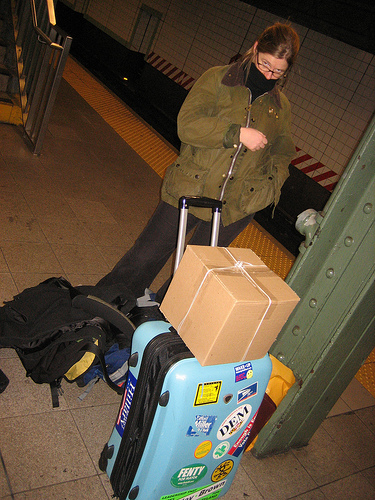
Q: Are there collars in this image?
A: Yes, there is a collar.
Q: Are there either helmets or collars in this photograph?
A: Yes, there is a collar.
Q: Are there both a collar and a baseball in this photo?
A: No, there is a collar but no baseballs.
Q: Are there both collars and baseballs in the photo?
A: No, there is a collar but no baseballs.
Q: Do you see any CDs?
A: No, there are no cds.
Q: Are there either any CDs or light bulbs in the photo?
A: No, there are no CDs or light bulbs.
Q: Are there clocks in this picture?
A: No, there are no clocks.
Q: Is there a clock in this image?
A: No, there are no clocks.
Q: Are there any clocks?
A: No, there are no clocks.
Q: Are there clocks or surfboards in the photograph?
A: No, there are no clocks or surfboards.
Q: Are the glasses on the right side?
A: Yes, the glasses are on the right of the image.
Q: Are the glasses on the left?
A: No, the glasses are on the right of the image.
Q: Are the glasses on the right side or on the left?
A: The glasses are on the right of the image.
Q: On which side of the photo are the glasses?
A: The glasses are on the right of the image.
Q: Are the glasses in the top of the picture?
A: Yes, the glasses are in the top of the image.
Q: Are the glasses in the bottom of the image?
A: No, the glasses are in the top of the image.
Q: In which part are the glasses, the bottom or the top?
A: The glasses are in the top of the image.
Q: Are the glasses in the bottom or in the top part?
A: The glasses are in the top of the image.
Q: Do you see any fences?
A: No, there are no fences.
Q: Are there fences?
A: No, there are no fences.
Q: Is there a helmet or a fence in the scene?
A: No, there are no fences or helmets.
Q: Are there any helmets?
A: No, there are no helmets.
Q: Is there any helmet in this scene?
A: No, there are no helmets.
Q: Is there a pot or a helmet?
A: No, there are no helmets or pots.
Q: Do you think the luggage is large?
A: Yes, the luggage is large.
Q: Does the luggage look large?
A: Yes, the luggage is large.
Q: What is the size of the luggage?
A: The luggage is large.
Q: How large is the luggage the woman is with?
A: The luggage is large.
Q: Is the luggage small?
A: No, the luggage is large.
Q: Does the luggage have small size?
A: No, the luggage is large.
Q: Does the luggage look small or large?
A: The luggage is large.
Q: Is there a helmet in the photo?
A: No, there are no helmets.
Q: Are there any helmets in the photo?
A: No, there are no helmets.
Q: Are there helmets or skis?
A: No, there are no helmets or skis.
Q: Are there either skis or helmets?
A: No, there are no helmets or skis.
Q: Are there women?
A: Yes, there is a woman.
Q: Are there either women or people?
A: Yes, there is a woman.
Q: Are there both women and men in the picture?
A: No, there is a woman but no men.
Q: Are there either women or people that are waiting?
A: Yes, the woman is waiting.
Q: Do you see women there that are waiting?
A: Yes, there is a woman that is waiting.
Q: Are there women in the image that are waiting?
A: Yes, there is a woman that is waiting.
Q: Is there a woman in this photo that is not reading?
A: Yes, there is a woman that is waiting.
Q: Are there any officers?
A: No, there are no officers.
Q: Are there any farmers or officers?
A: No, there are no officers or farmers.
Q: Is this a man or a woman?
A: This is a woman.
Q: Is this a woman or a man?
A: This is a woman.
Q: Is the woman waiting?
A: Yes, the woman is waiting.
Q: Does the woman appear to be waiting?
A: Yes, the woman is waiting.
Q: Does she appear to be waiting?
A: Yes, the woman is waiting.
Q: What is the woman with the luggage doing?
A: The woman is waiting.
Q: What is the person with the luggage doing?
A: The woman is waiting.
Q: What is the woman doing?
A: The woman is waiting.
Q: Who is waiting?
A: The woman is waiting.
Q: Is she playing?
A: No, the woman is waiting.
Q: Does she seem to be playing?
A: No, the woman is waiting.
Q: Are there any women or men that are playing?
A: No, there is a woman but she is waiting.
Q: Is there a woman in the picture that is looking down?
A: No, there is a woman but she is waiting.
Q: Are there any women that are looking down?
A: No, there is a woman but she is waiting.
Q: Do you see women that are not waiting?
A: No, there is a woman but she is waiting.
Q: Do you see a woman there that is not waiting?
A: No, there is a woman but she is waiting.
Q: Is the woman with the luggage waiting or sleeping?
A: The woman is waiting.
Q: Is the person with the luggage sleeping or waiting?
A: The woman is waiting.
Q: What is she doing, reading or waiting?
A: The woman is waiting.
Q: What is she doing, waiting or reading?
A: The woman is waiting.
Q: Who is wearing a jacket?
A: The woman is wearing a jacket.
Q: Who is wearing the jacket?
A: The woman is wearing a jacket.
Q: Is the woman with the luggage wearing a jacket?
A: Yes, the woman is wearing a jacket.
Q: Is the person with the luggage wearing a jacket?
A: Yes, the woman is wearing a jacket.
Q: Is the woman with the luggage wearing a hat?
A: No, the woman is wearing a jacket.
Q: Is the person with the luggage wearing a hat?
A: No, the woman is wearing a jacket.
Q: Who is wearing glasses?
A: The woman is wearing glasses.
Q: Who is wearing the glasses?
A: The woman is wearing glasses.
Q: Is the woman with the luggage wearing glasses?
A: Yes, the woman is wearing glasses.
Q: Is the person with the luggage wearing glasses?
A: Yes, the woman is wearing glasses.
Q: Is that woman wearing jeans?
A: No, the woman is wearing glasses.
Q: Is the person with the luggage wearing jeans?
A: No, the woman is wearing glasses.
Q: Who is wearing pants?
A: The woman is wearing pants.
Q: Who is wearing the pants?
A: The woman is wearing pants.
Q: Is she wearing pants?
A: Yes, the woman is wearing pants.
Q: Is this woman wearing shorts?
A: No, the woman is wearing pants.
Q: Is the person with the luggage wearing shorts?
A: No, the woman is wearing pants.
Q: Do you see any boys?
A: No, there are no boys.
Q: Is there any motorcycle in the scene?
A: No, there are no motorcycles.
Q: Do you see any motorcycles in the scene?
A: No, there are no motorcycles.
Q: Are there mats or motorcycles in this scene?
A: No, there are no motorcycles or mats.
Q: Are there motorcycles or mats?
A: No, there are no motorcycles or mats.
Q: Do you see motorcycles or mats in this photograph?
A: No, there are no motorcycles or mats.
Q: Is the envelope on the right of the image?
A: Yes, the envelope is on the right of the image.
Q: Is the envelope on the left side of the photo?
A: No, the envelope is on the right of the image.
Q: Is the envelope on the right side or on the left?
A: The envelope is on the right of the image.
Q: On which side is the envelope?
A: The envelope is on the right of the image.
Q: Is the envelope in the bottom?
A: Yes, the envelope is in the bottom of the image.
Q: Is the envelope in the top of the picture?
A: No, the envelope is in the bottom of the image.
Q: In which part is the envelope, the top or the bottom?
A: The envelope is in the bottom of the image.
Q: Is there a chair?
A: No, there are no chairs.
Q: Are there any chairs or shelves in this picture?
A: No, there are no chairs or shelves.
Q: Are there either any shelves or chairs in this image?
A: No, there are no chairs or shelves.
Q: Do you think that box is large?
A: Yes, the box is large.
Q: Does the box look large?
A: Yes, the box is large.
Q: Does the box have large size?
A: Yes, the box is large.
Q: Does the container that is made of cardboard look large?
A: Yes, the box is large.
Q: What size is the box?
A: The box is large.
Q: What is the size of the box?
A: The box is large.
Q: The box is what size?
A: The box is large.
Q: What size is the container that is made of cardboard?
A: The box is large.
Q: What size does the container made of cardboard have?
A: The box has large size.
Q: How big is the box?
A: The box is large.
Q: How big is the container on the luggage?
A: The box is large.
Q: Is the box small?
A: No, the box is large.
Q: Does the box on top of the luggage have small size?
A: No, the box is large.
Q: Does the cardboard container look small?
A: No, the box is large.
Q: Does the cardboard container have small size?
A: No, the box is large.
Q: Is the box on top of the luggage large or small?
A: The box is large.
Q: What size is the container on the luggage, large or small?
A: The box is large.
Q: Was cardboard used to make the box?
A: Yes, the box is made of cardboard.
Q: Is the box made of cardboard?
A: Yes, the box is made of cardboard.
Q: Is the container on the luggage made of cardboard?
A: Yes, the box is made of cardboard.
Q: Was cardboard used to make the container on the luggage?
A: Yes, the box is made of cardboard.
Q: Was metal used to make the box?
A: No, the box is made of cardboard.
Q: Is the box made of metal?
A: No, the box is made of cardboard.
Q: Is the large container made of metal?
A: No, the box is made of cardboard.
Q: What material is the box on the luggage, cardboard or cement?
A: The box is made of cardboard.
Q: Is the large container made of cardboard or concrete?
A: The box is made of cardboard.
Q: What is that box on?
A: The box is on the luggage.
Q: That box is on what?
A: The box is on the luggage.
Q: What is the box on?
A: The box is on the luggage.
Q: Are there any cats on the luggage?
A: No, there is a box on the luggage.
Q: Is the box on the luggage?
A: Yes, the box is on the luggage.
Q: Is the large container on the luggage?
A: Yes, the box is on the luggage.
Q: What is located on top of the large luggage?
A: The box is on top of the luggage.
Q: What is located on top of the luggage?
A: The box is on top of the luggage.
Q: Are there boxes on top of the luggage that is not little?
A: Yes, there is a box on top of the luggage.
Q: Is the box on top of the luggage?
A: Yes, the box is on top of the luggage.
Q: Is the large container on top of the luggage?
A: Yes, the box is on top of the luggage.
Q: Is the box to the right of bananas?
A: No, the box is to the right of the bags.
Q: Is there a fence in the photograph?
A: No, there are no fences.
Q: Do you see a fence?
A: No, there are no fences.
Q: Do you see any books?
A: No, there are no books.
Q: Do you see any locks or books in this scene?
A: No, there are no books or locks.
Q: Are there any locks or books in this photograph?
A: No, there are no books or locks.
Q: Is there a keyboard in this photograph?
A: No, there are no keyboards.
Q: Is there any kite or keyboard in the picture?
A: No, there are no keyboards or kites.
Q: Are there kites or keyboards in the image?
A: No, there are no keyboards or kites.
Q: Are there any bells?
A: No, there are no bells.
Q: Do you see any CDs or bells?
A: No, there are no bells or cds.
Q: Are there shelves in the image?
A: No, there are no shelves.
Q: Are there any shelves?
A: No, there are no shelves.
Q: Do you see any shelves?
A: No, there are no shelves.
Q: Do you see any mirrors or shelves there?
A: No, there are no shelves or mirrors.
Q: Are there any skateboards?
A: No, there are no skateboards.